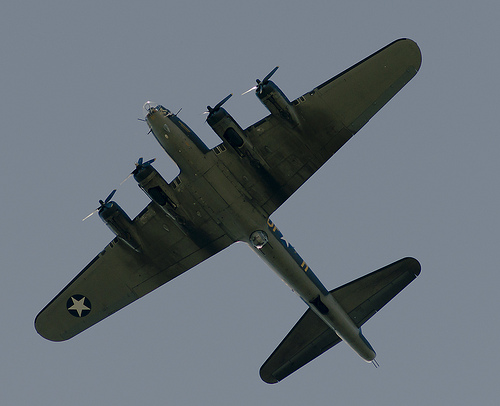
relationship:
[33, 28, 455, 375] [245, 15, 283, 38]
plane in air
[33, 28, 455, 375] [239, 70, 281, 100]
plane has propeller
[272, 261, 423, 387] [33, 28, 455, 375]
tail of plane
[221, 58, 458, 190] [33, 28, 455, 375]
wing of plane